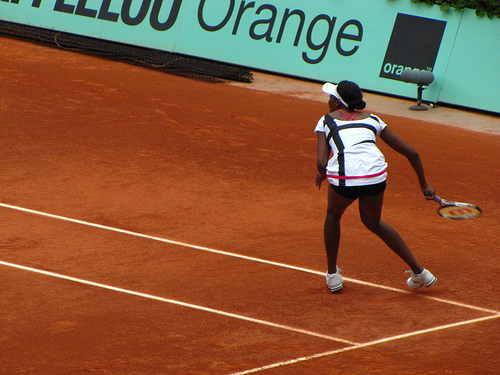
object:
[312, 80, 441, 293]
woman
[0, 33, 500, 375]
court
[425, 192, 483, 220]
racket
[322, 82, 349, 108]
hat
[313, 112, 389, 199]
outfit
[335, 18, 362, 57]
letter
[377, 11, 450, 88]
sign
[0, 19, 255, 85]
tarp